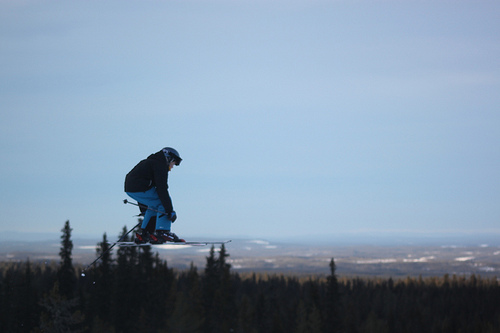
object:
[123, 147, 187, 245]
person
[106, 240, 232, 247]
skis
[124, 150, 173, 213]
coat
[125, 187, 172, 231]
pants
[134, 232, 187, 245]
shoes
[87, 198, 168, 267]
ski poles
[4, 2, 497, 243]
sky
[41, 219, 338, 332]
trees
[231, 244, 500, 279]
ground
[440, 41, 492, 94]
cloud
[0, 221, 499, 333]
forest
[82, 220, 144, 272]
pole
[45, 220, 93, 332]
tree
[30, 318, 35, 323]
corner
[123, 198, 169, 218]
ski pole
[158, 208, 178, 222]
hand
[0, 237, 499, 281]
hills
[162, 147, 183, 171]
helmet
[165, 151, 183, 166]
goggles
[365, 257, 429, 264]
snow